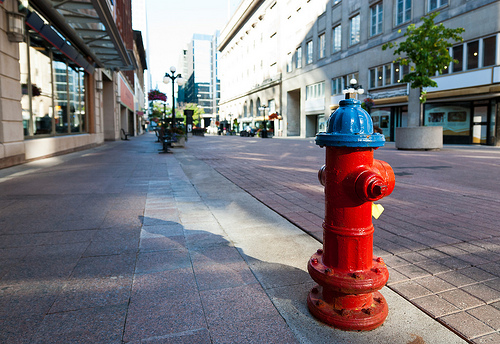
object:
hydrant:
[309, 91, 398, 331]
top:
[314, 92, 387, 148]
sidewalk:
[3, 124, 465, 342]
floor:
[178, 129, 499, 343]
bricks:
[416, 259, 452, 274]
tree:
[380, 10, 466, 124]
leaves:
[427, 33, 430, 38]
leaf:
[417, 49, 420, 54]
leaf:
[428, 41, 431, 48]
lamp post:
[162, 65, 184, 132]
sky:
[127, 0, 242, 90]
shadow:
[139, 216, 316, 320]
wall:
[454, 8, 499, 35]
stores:
[2, 11, 106, 163]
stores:
[414, 94, 498, 146]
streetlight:
[258, 104, 271, 131]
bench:
[156, 128, 177, 153]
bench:
[121, 128, 133, 140]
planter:
[396, 126, 444, 151]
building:
[225, 3, 499, 149]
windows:
[480, 34, 498, 66]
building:
[2, 2, 148, 168]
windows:
[16, 27, 100, 138]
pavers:
[434, 255, 497, 295]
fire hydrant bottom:
[308, 147, 395, 331]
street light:
[228, 112, 233, 131]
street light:
[157, 101, 169, 127]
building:
[176, 31, 221, 133]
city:
[0, 1, 498, 343]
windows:
[198, 100, 213, 107]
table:
[192, 127, 207, 136]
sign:
[425, 105, 472, 139]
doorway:
[101, 70, 117, 143]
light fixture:
[6, 11, 26, 43]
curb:
[174, 147, 455, 343]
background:
[2, 0, 498, 164]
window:
[332, 23, 341, 54]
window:
[350, 14, 360, 46]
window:
[369, 2, 383, 37]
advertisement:
[445, 105, 472, 136]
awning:
[147, 89, 166, 101]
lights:
[396, 68, 400, 72]